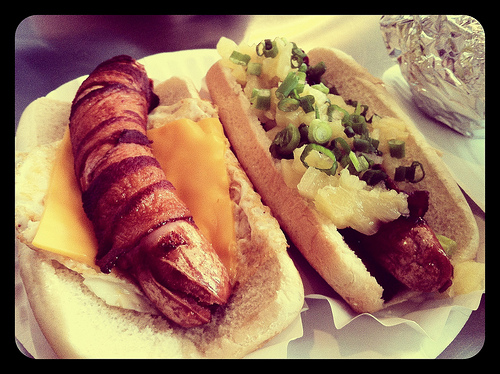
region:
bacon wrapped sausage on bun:
[18, 34, 345, 371]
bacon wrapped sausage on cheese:
[60, 39, 286, 366]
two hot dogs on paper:
[22, 15, 481, 372]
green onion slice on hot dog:
[335, 88, 377, 148]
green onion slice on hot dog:
[305, 53, 328, 79]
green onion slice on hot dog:
[281, 60, 316, 97]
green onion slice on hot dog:
[249, 73, 273, 115]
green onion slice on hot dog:
[234, 39, 249, 73]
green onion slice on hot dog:
[256, 35, 277, 54]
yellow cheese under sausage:
[140, 90, 242, 280]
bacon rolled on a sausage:
[73, 51, 235, 328]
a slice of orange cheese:
[34, 110, 236, 282]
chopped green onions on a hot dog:
[227, 38, 404, 172]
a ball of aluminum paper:
[376, 16, 487, 138]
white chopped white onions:
[292, 145, 408, 233]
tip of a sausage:
[370, 212, 452, 289]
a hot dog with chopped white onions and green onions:
[206, 27, 481, 310]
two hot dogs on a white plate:
[18, 42, 480, 356]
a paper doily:
[295, 253, 485, 333]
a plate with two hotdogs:
[30, 41, 491, 358]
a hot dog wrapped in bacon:
[67, 73, 234, 323]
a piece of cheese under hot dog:
[53, 101, 251, 295]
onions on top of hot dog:
[242, 38, 419, 236]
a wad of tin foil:
[380, 11, 495, 122]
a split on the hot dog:
[138, 250, 228, 325]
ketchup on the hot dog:
[393, 224, 444, 291]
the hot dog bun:
[227, 163, 300, 353]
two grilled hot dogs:
[61, 56, 431, 325]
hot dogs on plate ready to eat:
[23, 44, 499, 322]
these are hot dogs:
[38, 50, 461, 326]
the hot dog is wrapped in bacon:
[55, 67, 230, 304]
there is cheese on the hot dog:
[30, 114, 270, 346]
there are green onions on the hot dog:
[243, 47, 423, 255]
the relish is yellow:
[299, 165, 394, 213]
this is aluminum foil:
[377, 30, 480, 108]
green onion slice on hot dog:
[340, 101, 380, 151]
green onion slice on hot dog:
[300, 133, 347, 182]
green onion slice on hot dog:
[282, 70, 309, 106]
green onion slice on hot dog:
[271, 111, 307, 175]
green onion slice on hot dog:
[290, 38, 313, 85]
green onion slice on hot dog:
[255, 26, 276, 58]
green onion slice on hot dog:
[245, 83, 271, 115]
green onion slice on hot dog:
[219, 36, 254, 71]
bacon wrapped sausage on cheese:
[46, 36, 286, 333]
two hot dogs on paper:
[6, 30, 498, 372]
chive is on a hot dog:
[409, 160, 425, 181]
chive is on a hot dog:
[303, 144, 339, 176]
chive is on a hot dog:
[310, 116, 330, 140]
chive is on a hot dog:
[254, 87, 271, 108]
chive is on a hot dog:
[277, 70, 307, 101]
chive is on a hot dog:
[344, 114, 362, 125]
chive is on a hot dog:
[325, 102, 348, 120]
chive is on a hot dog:
[314, 98, 334, 120]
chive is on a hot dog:
[259, 39, 276, 54]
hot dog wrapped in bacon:
[66, 51, 228, 326]